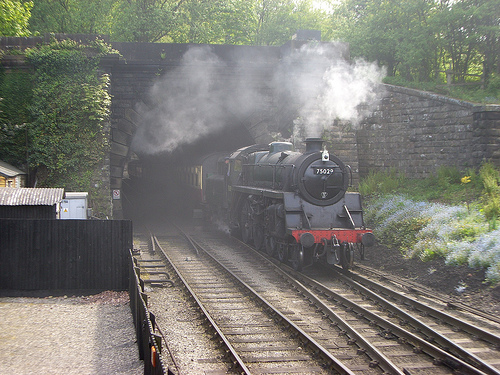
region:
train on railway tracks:
[124, 135, 381, 273]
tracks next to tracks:
[128, 170, 354, 373]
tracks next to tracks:
[177, 190, 498, 373]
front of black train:
[297, 152, 350, 204]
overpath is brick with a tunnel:
[2, 29, 498, 220]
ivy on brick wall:
[2, 35, 123, 218]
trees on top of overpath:
[0, 0, 498, 91]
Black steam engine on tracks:
[213, 135, 377, 276]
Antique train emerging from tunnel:
[141, 135, 377, 274]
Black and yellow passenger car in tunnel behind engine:
[176, 150, 226, 211]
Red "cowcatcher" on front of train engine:
[288, 228, 377, 246]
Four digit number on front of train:
[313, 167, 333, 175]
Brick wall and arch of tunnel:
[0, 35, 499, 217]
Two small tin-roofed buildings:
[1, 158, 68, 220]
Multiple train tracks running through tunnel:
[122, 175, 499, 374]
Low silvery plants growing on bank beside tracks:
[363, 192, 498, 283]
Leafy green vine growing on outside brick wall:
[26, 34, 126, 175]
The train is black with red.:
[196, 138, 376, 270]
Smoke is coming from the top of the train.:
[258, 54, 377, 144]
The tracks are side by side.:
[126, 213, 496, 374]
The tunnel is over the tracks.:
[115, 82, 272, 244]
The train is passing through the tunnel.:
[108, 42, 378, 266]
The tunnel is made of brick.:
[99, 36, 305, 246]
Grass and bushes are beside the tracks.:
[358, 164, 499, 289]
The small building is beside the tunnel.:
[2, 154, 132, 295]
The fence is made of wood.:
[3, 215, 133, 297]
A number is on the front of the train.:
[312, 163, 337, 178]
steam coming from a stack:
[129, 32, 385, 149]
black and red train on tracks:
[177, 140, 375, 270]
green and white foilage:
[353, 159, 498, 293]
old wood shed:
[1, 185, 68, 217]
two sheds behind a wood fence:
[0, 158, 130, 293]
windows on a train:
[170, 163, 203, 190]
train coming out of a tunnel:
[122, 72, 374, 279]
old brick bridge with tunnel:
[2, 31, 498, 223]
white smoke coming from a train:
[128, 35, 387, 270]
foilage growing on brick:
[0, 27, 124, 224]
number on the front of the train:
[313, 165, 338, 181]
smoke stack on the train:
[302, 135, 324, 152]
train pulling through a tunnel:
[118, 128, 379, 276]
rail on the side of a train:
[235, 161, 303, 190]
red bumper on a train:
[286, 228, 374, 248]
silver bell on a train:
[321, 144, 333, 164]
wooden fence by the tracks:
[4, 212, 135, 304]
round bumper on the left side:
[298, 230, 316, 250]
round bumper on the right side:
[359, 229, 375, 251]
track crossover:
[316, 277, 499, 374]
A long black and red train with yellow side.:
[126, 137, 375, 270]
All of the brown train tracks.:
[119, 178, 499, 373]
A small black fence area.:
[1, 219, 133, 299]